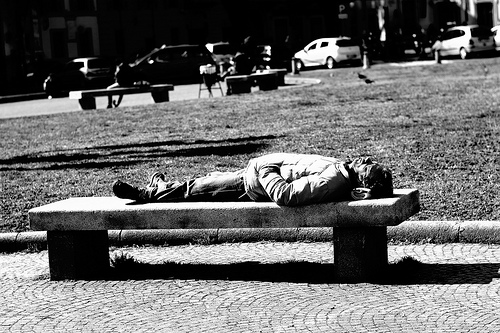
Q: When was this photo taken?
A: During the day.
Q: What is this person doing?
A: Laying down.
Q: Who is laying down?
A: A man.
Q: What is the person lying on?
A: A bench.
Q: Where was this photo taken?
A: In a park.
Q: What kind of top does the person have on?
A: A coat.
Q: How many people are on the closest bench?
A: One.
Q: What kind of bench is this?
A: Concrete.